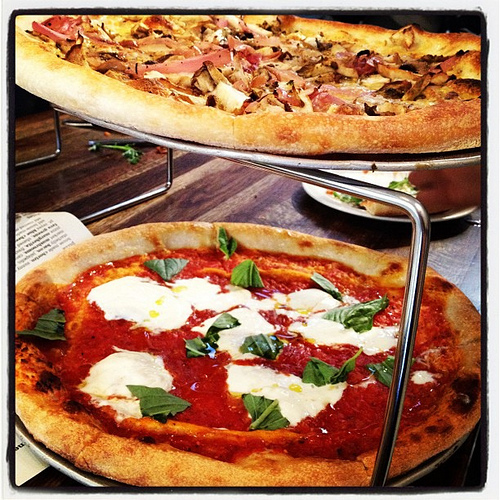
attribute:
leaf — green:
[126, 383, 190, 419]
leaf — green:
[241, 392, 288, 430]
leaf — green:
[233, 259, 263, 289]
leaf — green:
[148, 258, 188, 278]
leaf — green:
[18, 306, 65, 343]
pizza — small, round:
[13, 9, 476, 153]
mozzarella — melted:
[75, 340, 178, 430]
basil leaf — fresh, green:
[325, 295, 389, 328]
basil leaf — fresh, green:
[230, 255, 265, 287]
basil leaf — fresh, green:
[211, 225, 238, 257]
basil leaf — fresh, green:
[125, 383, 190, 420]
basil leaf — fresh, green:
[241, 392, 290, 432]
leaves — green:
[321, 295, 388, 330]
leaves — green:
[241, 390, 292, 433]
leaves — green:
[230, 255, 265, 287]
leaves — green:
[144, 255, 189, 280]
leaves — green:
[124, 382, 190, 414]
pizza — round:
[4, 221, 482, 483]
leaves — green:
[319, 281, 391, 330]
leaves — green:
[120, 363, 197, 428]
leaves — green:
[242, 381, 294, 433]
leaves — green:
[302, 334, 364, 385]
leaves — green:
[225, 251, 270, 291]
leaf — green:
[215, 224, 240, 261]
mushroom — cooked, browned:
[361, 99, 394, 118]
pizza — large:
[13, 15, 470, 182]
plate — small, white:
[301, 182, 358, 219]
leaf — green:
[207, 221, 239, 266]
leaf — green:
[227, 254, 267, 294]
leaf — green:
[320, 290, 397, 334]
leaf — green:
[137, 250, 194, 285]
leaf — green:
[13, 297, 71, 347]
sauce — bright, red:
[28, 245, 459, 465]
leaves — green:
[19, 305, 71, 347]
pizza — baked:
[50, 29, 473, 146]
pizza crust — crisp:
[59, 238, 124, 267]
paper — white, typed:
[11, 194, 96, 280]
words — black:
[28, 219, 49, 248]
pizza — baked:
[38, 188, 485, 478]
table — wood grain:
[173, 159, 227, 199]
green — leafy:
[126, 382, 190, 422]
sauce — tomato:
[187, 363, 216, 398]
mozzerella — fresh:
[114, 281, 173, 319]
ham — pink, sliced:
[146, 47, 229, 77]